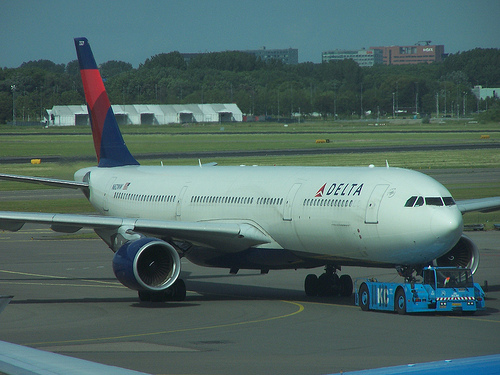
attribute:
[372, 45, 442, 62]
building — tall, large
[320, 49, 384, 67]
building — tall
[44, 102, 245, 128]
building — grey, white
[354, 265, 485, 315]
service vehicle — blue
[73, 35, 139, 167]
tail — red, orage, brown, blue, maroon, orange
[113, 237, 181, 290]
turbine engine — blue, round, huge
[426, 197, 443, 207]
window — wide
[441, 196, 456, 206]
window — wide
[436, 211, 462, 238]
airplane nose — white